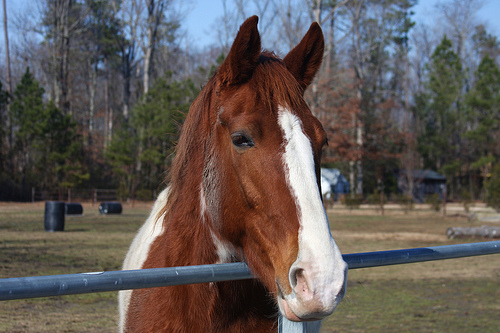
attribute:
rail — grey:
[12, 216, 499, 305]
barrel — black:
[34, 173, 103, 249]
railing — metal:
[1, 222, 428, 296]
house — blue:
[308, 140, 455, 220]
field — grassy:
[1, 185, 426, 329]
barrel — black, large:
[41, 197, 71, 247]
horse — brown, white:
[137, 20, 384, 330]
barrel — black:
[40, 197, 67, 234]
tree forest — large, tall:
[6, 25, 167, 206]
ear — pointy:
[224, 11, 269, 75]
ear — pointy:
[282, 22, 352, 109]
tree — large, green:
[10, 60, 88, 216]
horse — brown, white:
[173, 3, 396, 322]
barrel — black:
[37, 196, 68, 239]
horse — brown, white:
[162, 5, 380, 330]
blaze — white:
[257, 90, 333, 264]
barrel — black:
[33, 194, 68, 234]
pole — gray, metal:
[1, 234, 496, 305]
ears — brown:
[230, 9, 324, 90]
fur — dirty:
[198, 142, 223, 232]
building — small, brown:
[116, 22, 349, 331]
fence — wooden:
[5, 179, 496, 199]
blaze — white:
[276, 105, 350, 312]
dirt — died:
[200, 136, 220, 239]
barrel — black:
[43, 193, 73, 233]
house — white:
[317, 163, 350, 205]